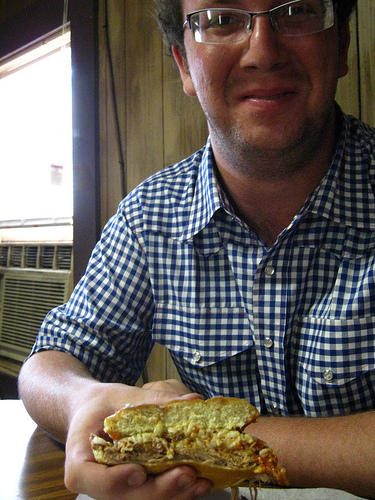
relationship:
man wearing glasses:
[16, 0, 373, 497] [175, 1, 336, 47]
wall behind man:
[72, 1, 373, 388] [16, 0, 373, 497]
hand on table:
[63, 378, 216, 499] [1, 385, 95, 490]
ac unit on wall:
[0, 235, 72, 345] [1, 157, 96, 358]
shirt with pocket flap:
[42, 120, 373, 421] [151, 304, 252, 365]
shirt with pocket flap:
[42, 120, 373, 421] [298, 319, 373, 385]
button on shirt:
[318, 364, 338, 385] [42, 120, 373, 421]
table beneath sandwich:
[0, 401, 280, 498] [88, 395, 291, 498]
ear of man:
[168, 43, 197, 94] [16, 0, 373, 497]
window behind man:
[6, 20, 92, 236] [16, 0, 373, 497]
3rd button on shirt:
[258, 334, 276, 350] [42, 120, 373, 421]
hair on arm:
[137, 1, 192, 56] [268, 415, 360, 482]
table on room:
[0, 401, 375, 500] [1, 4, 361, 498]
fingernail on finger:
[115, 456, 229, 496] [46, 449, 154, 495]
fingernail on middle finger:
[174, 469, 198, 490] [118, 461, 199, 499]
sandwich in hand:
[88, 396, 290, 500] [90, 393, 291, 493]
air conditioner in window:
[2, 226, 72, 357] [2, 45, 74, 246]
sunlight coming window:
[1, 37, 83, 225] [6, 22, 90, 253]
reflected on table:
[0, 402, 44, 498] [0, 399, 79, 499]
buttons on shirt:
[238, 248, 291, 392] [111, 174, 353, 344]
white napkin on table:
[218, 487, 368, 499] [0, 395, 372, 498]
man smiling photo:
[17, 0, 375, 499] [3, 4, 361, 494]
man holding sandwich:
[17, 0, 375, 499] [89, 398, 262, 479]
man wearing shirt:
[16, 0, 373, 497] [42, 120, 373, 421]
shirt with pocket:
[42, 120, 373, 421] [151, 303, 261, 414]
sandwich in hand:
[88, 395, 291, 498] [63, 385, 231, 496]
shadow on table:
[17, 420, 76, 497] [0, 395, 72, 498]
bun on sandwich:
[103, 396, 253, 430] [86, 389, 287, 492]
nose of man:
[239, 17, 291, 69] [16, 0, 373, 497]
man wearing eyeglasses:
[16, 0, 373, 497] [175, 0, 347, 47]